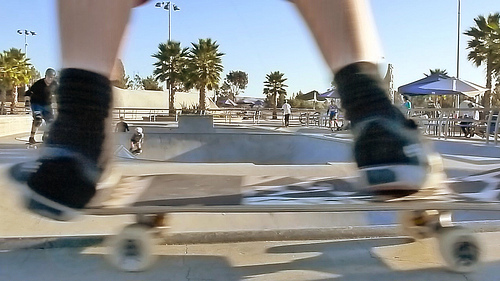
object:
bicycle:
[298, 110, 321, 125]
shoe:
[353, 113, 447, 193]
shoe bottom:
[364, 184, 419, 194]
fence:
[102, 104, 316, 121]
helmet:
[43, 68, 57, 77]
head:
[45, 67, 56, 84]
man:
[402, 95, 412, 112]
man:
[280, 100, 291, 126]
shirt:
[402, 101, 410, 111]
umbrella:
[419, 75, 485, 118]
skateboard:
[83, 167, 500, 270]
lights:
[30, 30, 39, 36]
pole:
[24, 33, 28, 59]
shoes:
[7, 151, 95, 221]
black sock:
[333, 59, 400, 126]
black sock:
[43, 68, 116, 166]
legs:
[48, 0, 154, 160]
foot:
[355, 116, 443, 192]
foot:
[5, 156, 106, 223]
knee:
[34, 116, 43, 126]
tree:
[459, 10, 499, 138]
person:
[6, 0, 444, 224]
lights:
[172, 5, 183, 11]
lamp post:
[164, 1, 178, 117]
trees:
[178, 38, 224, 113]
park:
[0, 0, 500, 280]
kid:
[23, 67, 58, 145]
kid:
[127, 125, 145, 152]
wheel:
[102, 225, 164, 272]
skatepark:
[0, 114, 492, 277]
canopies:
[398, 75, 488, 97]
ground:
[0, 232, 500, 280]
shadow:
[1, 230, 500, 280]